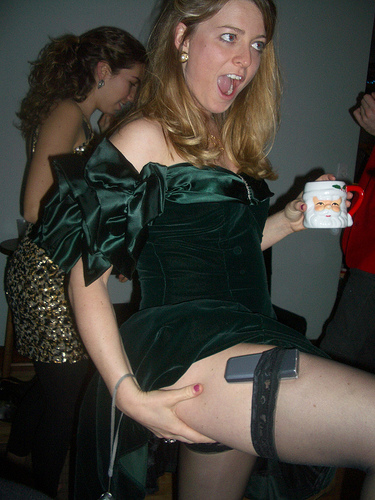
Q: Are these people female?
A: No, they are both male and female.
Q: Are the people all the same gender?
A: No, they are both male and female.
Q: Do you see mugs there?
A: Yes, there is a mug.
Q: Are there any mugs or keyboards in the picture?
A: Yes, there is a mug.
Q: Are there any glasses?
A: No, there are no glasses.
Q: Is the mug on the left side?
A: No, the mug is on the right of the image.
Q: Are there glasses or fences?
A: No, there are no glasses or fences.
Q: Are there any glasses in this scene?
A: No, there are no glasses.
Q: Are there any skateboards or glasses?
A: No, there are no glasses or skateboards.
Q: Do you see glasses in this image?
A: No, there are no glasses.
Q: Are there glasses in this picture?
A: No, there are no glasses.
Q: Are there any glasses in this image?
A: No, there are no glasses.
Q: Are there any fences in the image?
A: No, there are no fences.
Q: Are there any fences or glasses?
A: No, there are no fences or glasses.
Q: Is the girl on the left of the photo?
A: Yes, the girl is on the left of the image.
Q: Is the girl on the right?
A: No, the girl is on the left of the image.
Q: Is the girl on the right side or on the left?
A: The girl is on the left of the image.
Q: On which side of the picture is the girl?
A: The girl is on the left of the image.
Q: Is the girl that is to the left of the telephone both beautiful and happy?
A: Yes, the girl is beautiful and happy.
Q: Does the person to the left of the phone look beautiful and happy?
A: Yes, the girl is beautiful and happy.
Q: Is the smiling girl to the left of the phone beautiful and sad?
A: No, the girl is beautiful but happy.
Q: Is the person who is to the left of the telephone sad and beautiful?
A: No, the girl is beautiful but happy.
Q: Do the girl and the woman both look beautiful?
A: Yes, both the girl and the woman are beautiful.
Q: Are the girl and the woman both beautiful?
A: Yes, both the girl and the woman are beautiful.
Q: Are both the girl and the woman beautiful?
A: Yes, both the girl and the woman are beautiful.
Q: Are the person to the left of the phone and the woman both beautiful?
A: Yes, both the girl and the woman are beautiful.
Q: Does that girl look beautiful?
A: Yes, the girl is beautiful.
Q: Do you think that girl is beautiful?
A: Yes, the girl is beautiful.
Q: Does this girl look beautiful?
A: Yes, the girl is beautiful.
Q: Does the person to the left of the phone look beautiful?
A: Yes, the girl is beautiful.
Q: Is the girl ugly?
A: No, the girl is beautiful.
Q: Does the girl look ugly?
A: No, the girl is beautiful.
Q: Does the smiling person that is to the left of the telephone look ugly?
A: No, the girl is beautiful.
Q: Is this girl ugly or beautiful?
A: The girl is beautiful.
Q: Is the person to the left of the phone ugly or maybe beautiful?
A: The girl is beautiful.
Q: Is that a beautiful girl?
A: Yes, that is a beautiful girl.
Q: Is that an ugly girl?
A: No, that is a beautiful girl.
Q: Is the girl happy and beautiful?
A: Yes, the girl is happy and beautiful.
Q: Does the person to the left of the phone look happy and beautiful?
A: Yes, the girl is happy and beautiful.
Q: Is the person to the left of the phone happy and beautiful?
A: Yes, the girl is happy and beautiful.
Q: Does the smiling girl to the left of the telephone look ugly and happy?
A: No, the girl is happy but beautiful.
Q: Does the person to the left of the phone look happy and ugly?
A: No, the girl is happy but beautiful.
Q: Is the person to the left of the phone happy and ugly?
A: No, the girl is happy but beautiful.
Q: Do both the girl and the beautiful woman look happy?
A: Yes, both the girl and the woman are happy.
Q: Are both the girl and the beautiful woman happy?
A: Yes, both the girl and the woman are happy.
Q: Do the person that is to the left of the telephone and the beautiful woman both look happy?
A: Yes, both the girl and the woman are happy.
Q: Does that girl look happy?
A: Yes, the girl is happy.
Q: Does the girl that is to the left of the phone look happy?
A: Yes, the girl is happy.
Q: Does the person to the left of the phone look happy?
A: Yes, the girl is happy.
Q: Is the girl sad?
A: No, the girl is happy.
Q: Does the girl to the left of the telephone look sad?
A: No, the girl is happy.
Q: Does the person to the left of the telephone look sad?
A: No, the girl is happy.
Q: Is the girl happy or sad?
A: The girl is happy.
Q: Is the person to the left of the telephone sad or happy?
A: The girl is happy.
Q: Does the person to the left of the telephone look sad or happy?
A: The girl is happy.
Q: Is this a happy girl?
A: Yes, this is a happy girl.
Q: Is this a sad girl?
A: No, this is a happy girl.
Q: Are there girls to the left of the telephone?
A: Yes, there is a girl to the left of the telephone.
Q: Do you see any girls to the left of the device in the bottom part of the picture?
A: Yes, there is a girl to the left of the telephone.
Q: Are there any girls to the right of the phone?
A: No, the girl is to the left of the phone.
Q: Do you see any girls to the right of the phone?
A: No, the girl is to the left of the phone.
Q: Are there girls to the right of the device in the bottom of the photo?
A: No, the girl is to the left of the phone.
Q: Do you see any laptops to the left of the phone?
A: No, there is a girl to the left of the phone.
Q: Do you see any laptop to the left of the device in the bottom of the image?
A: No, there is a girl to the left of the phone.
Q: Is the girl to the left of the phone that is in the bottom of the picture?
A: Yes, the girl is to the left of the telephone.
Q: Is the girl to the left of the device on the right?
A: Yes, the girl is to the left of the telephone.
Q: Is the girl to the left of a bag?
A: No, the girl is to the left of the telephone.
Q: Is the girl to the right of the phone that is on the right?
A: No, the girl is to the left of the telephone.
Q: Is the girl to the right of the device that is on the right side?
A: No, the girl is to the left of the telephone.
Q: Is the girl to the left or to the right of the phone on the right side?
A: The girl is to the left of the phone.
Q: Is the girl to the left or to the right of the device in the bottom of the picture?
A: The girl is to the left of the phone.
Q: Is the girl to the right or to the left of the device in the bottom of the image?
A: The girl is to the left of the phone.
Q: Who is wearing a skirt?
A: The girl is wearing a skirt.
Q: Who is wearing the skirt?
A: The girl is wearing a skirt.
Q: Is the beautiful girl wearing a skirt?
A: Yes, the girl is wearing a skirt.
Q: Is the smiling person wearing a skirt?
A: Yes, the girl is wearing a skirt.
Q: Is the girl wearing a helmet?
A: No, the girl is wearing a skirt.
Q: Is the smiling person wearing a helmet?
A: No, the girl is wearing a skirt.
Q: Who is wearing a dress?
A: The girl is wearing a dress.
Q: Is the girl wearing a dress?
A: Yes, the girl is wearing a dress.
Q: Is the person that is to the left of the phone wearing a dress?
A: Yes, the girl is wearing a dress.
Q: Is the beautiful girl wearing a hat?
A: No, the girl is wearing a dress.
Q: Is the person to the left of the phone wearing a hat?
A: No, the girl is wearing a dress.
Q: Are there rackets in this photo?
A: No, there are no rackets.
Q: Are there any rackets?
A: No, there are no rackets.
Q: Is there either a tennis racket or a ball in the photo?
A: No, there are no rackets or balls.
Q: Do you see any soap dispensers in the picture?
A: No, there are no soap dispensers.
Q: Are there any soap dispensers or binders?
A: No, there are no soap dispensers or binders.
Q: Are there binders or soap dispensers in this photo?
A: No, there are no soap dispensers or binders.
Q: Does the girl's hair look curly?
A: Yes, the hair is curly.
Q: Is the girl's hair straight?
A: No, the hair is curly.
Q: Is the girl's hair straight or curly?
A: The hair is curly.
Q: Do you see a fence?
A: No, there are no fences.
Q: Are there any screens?
A: No, there are no screens.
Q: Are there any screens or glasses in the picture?
A: No, there are no screens or glasses.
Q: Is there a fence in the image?
A: No, there are no fences.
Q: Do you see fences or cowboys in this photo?
A: No, there are no fences or cowboys.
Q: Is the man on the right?
A: Yes, the man is on the right of the image.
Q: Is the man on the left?
A: No, the man is on the right of the image.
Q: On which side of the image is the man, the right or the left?
A: The man is on the right of the image.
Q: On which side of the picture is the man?
A: The man is on the right of the image.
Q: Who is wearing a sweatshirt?
A: The man is wearing a sweatshirt.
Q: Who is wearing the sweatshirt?
A: The man is wearing a sweatshirt.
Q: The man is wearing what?
A: The man is wearing a sweatshirt.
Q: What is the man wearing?
A: The man is wearing a sweatshirt.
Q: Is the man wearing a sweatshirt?
A: Yes, the man is wearing a sweatshirt.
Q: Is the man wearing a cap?
A: No, the man is wearing a sweatshirt.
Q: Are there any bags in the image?
A: No, there are no bags.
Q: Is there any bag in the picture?
A: No, there are no bags.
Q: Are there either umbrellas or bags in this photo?
A: No, there are no bags or umbrellas.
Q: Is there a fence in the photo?
A: No, there are no fences.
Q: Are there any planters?
A: No, there are no planters.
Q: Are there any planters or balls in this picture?
A: No, there are no planters or balls.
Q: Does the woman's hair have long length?
A: Yes, the hair is long.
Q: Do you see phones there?
A: Yes, there is a phone.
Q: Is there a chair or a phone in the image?
A: Yes, there is a phone.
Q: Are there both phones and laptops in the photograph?
A: No, there is a phone but no laptops.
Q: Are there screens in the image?
A: No, there are no screens.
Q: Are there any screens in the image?
A: No, there are no screens.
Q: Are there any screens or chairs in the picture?
A: No, there are no screens or chairs.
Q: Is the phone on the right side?
A: Yes, the phone is on the right of the image.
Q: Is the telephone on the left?
A: No, the telephone is on the right of the image.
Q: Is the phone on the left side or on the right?
A: The phone is on the right of the image.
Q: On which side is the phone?
A: The phone is on the right of the image.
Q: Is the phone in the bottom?
A: Yes, the phone is in the bottom of the image.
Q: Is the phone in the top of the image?
A: No, the phone is in the bottom of the image.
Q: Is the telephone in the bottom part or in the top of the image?
A: The telephone is in the bottom of the image.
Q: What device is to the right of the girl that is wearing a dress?
A: The device is a phone.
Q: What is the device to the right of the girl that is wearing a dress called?
A: The device is a phone.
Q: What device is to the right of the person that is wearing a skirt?
A: The device is a phone.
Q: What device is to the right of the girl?
A: The device is a phone.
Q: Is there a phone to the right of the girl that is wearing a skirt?
A: Yes, there is a phone to the right of the girl.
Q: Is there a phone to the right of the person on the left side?
A: Yes, there is a phone to the right of the girl.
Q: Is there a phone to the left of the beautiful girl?
A: No, the phone is to the right of the girl.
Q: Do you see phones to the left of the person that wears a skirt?
A: No, the phone is to the right of the girl.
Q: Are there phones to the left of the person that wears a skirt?
A: No, the phone is to the right of the girl.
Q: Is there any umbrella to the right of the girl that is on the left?
A: No, there is a phone to the right of the girl.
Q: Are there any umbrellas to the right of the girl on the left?
A: No, there is a phone to the right of the girl.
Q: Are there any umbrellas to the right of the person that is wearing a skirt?
A: No, there is a phone to the right of the girl.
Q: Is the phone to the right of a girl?
A: Yes, the phone is to the right of a girl.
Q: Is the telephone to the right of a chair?
A: No, the telephone is to the right of a girl.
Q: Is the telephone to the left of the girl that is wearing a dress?
A: No, the telephone is to the right of the girl.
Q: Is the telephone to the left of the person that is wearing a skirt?
A: No, the telephone is to the right of the girl.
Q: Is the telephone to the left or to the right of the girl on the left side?
A: The telephone is to the right of the girl.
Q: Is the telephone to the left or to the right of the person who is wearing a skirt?
A: The telephone is to the right of the girl.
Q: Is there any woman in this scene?
A: Yes, there is a woman.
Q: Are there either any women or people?
A: Yes, there is a woman.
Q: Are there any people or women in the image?
A: Yes, there is a woman.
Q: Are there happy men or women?
A: Yes, there is a happy woman.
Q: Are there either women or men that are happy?
A: Yes, the woman is happy.